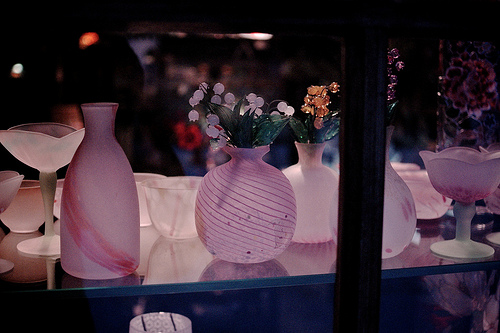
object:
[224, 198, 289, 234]
pattern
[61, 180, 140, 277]
color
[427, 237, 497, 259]
base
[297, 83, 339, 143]
stalks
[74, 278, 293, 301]
edge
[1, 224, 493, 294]
top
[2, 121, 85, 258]
vase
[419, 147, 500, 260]
vase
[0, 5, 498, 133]
background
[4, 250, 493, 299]
shelf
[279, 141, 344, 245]
vase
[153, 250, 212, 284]
counter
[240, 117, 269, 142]
leaves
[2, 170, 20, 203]
glass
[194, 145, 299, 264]
vase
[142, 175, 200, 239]
cup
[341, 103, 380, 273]
pole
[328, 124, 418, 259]
vase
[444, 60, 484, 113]
flower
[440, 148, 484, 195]
glass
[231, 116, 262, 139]
stems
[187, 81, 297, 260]
plants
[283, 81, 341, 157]
plants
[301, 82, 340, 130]
flowers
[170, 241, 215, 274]
surface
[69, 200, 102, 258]
stripe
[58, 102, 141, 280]
vase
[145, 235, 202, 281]
table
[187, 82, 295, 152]
flowers